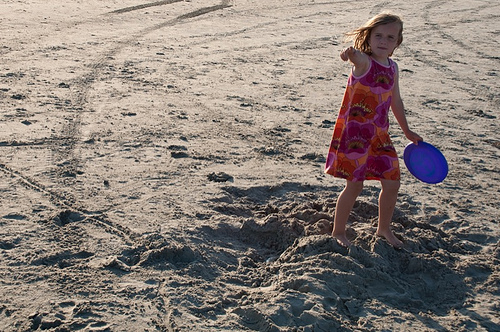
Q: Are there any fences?
A: No, there are no fences.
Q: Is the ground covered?
A: Yes, the ground is covered.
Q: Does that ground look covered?
A: Yes, the ground is covered.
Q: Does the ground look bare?
A: No, the ground is covered.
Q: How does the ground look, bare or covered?
A: The ground is covered.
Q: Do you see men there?
A: No, there are no men.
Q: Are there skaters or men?
A: No, there are no men or skaters.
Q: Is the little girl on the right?
A: Yes, the girl is on the right of the image.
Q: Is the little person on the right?
A: Yes, the girl is on the right of the image.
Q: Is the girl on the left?
A: No, the girl is on the right of the image.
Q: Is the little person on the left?
A: No, the girl is on the right of the image.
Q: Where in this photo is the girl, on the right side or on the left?
A: The girl is on the right of the image.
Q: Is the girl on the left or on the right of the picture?
A: The girl is on the right of the image.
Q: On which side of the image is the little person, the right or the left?
A: The girl is on the right of the image.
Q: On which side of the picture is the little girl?
A: The girl is on the right of the image.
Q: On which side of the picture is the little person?
A: The girl is on the right of the image.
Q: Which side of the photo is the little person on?
A: The girl is on the right of the image.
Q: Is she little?
A: Yes, the girl is little.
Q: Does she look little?
A: Yes, the girl is little.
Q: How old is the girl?
A: The girl is little.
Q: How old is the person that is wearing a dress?
A: The girl is little.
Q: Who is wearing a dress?
A: The girl is wearing a dress.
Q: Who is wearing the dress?
A: The girl is wearing a dress.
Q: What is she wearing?
A: The girl is wearing a dress.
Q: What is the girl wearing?
A: The girl is wearing a dress.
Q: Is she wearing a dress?
A: Yes, the girl is wearing a dress.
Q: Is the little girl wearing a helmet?
A: No, the girl is wearing a dress.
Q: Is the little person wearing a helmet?
A: No, the girl is wearing a dress.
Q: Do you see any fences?
A: No, there are no fences.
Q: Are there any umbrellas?
A: No, there are no umbrellas.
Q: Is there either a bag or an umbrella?
A: No, there are no umbrellas or bags.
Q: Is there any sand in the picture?
A: Yes, there is sand.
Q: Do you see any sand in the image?
A: Yes, there is sand.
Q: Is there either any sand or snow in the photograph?
A: Yes, there is sand.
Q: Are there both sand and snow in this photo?
A: No, there is sand but no snow.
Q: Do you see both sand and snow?
A: No, there is sand but no snow.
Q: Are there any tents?
A: No, there are no tents.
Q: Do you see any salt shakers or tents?
A: No, there are no tents or salt shakers.